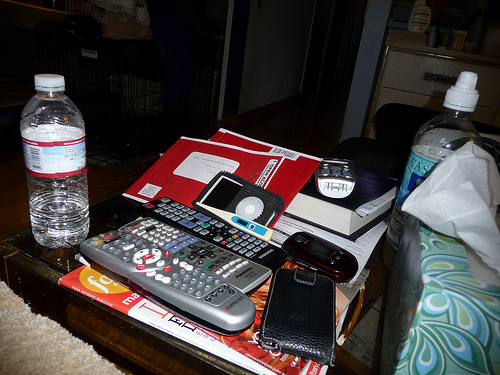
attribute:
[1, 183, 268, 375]
table — wooden, cluttered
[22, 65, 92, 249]
water bottle — closed, plastic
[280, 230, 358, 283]
cellphone — rounded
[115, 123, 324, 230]
letters — red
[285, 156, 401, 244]
book — thick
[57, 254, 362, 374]
magazine — orange, white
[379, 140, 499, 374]
tissue box — blue, green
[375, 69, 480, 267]
bottle — plastic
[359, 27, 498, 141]
dresser — tan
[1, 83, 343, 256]
floor — wooden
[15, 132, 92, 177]
label — red, white, blue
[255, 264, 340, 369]
wallet — leather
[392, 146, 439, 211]
label — blue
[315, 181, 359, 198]
edges — rounded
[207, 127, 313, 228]
mail — from netflix